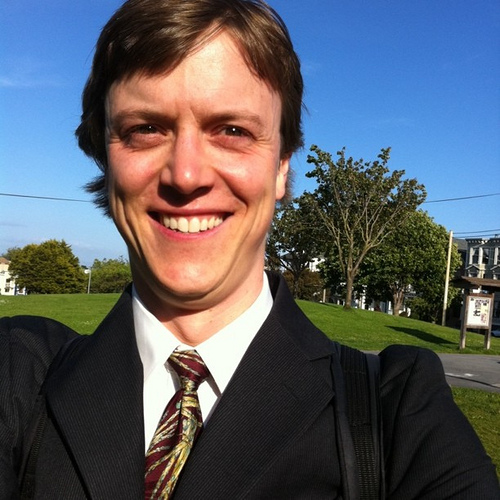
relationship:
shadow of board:
[387, 323, 458, 352] [456, 291, 497, 352]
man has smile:
[2, 2, 499, 498] [141, 200, 238, 246]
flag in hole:
[81, 268, 95, 293] [82, 292, 94, 297]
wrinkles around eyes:
[252, 131, 276, 157] [121, 114, 257, 149]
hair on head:
[117, 8, 175, 62] [73, 3, 319, 310]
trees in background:
[267, 145, 447, 324] [312, 301, 489, 353]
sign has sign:
[466, 294, 495, 327] [466, 294, 495, 327]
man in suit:
[2, 2, 499, 498] [0, 279, 497, 497]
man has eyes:
[2, 2, 499, 498] [121, 114, 257, 149]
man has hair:
[2, 2, 499, 498] [117, 8, 175, 62]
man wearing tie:
[2, 2, 499, 498] [142, 340, 206, 498]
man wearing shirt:
[2, 2, 499, 498] [128, 271, 277, 471]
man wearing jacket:
[2, 2, 499, 498] [0, 269, 500, 498]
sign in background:
[466, 294, 495, 327] [312, 301, 489, 353]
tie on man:
[142, 340, 206, 498] [2, 2, 499, 498]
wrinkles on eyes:
[252, 131, 276, 157] [121, 114, 257, 149]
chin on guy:
[153, 258, 230, 305] [2, 2, 499, 498]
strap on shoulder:
[321, 339, 394, 499] [306, 327, 453, 426]